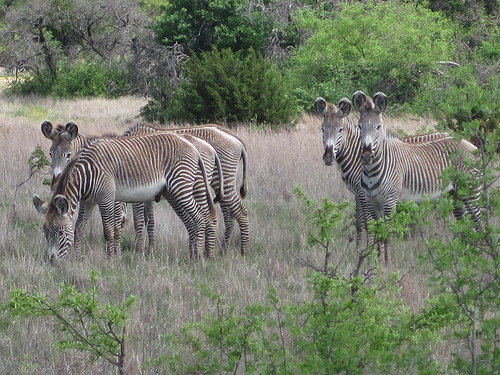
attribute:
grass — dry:
[376, 241, 449, 283]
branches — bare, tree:
[114, 12, 146, 50]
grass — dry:
[128, 251, 310, 373]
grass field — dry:
[255, 138, 315, 199]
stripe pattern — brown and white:
[358, 159, 388, 190]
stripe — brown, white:
[166, 173, 194, 184]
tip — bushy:
[239, 183, 248, 199]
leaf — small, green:
[304, 280, 312, 285]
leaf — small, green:
[330, 283, 334, 287]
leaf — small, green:
[369, 316, 374, 321]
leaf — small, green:
[330, 346, 335, 350]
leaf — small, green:
[366, 220, 372, 225]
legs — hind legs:
[169, 187, 206, 257]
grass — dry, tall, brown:
[0, 77, 499, 373]